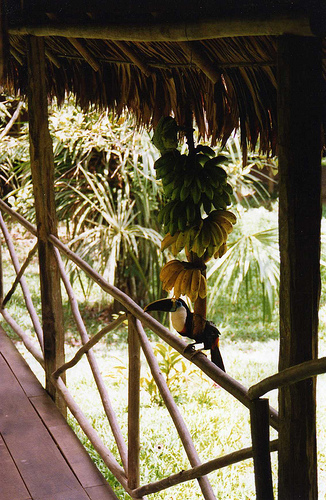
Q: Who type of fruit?
A: Bananas.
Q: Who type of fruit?
A: Bananas.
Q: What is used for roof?
A: Leaves.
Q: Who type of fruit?
A: Bananas.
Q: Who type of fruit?
A: Bananas.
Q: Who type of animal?
A: Bird.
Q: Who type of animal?
A: Bird.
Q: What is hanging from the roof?
A: Banana.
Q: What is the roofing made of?
A: Leaves.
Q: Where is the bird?
A: Railing.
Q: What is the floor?
A: Wooden.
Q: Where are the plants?
A: Near the tent.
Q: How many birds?
A: One.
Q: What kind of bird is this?
A: Toucan.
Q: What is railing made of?
A: Bamboo.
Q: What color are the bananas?
A: Green and yellow.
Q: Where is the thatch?
A: On roof.